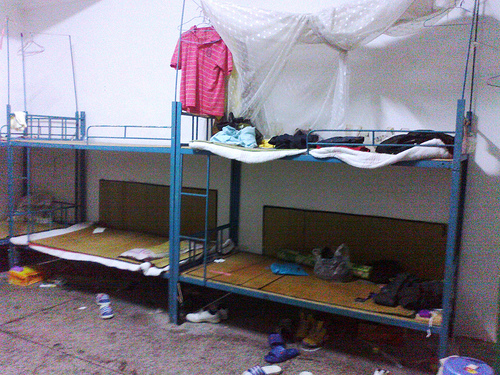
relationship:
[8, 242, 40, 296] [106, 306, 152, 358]
box on floor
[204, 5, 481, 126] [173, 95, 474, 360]
sheet over bed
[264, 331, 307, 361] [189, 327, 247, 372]
sandals are on floor